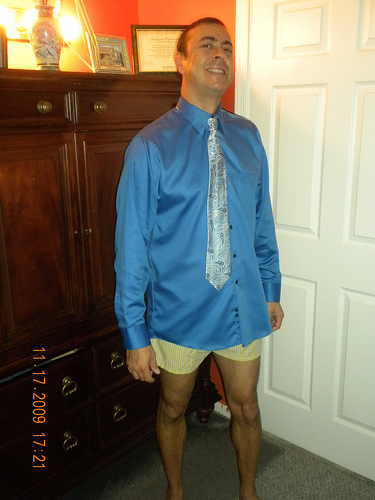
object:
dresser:
[0, 69, 223, 365]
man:
[113, 17, 285, 500]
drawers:
[96, 380, 159, 456]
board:
[98, 5, 125, 27]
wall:
[2, 0, 137, 68]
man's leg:
[149, 333, 201, 499]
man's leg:
[213, 337, 262, 500]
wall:
[223, 89, 235, 108]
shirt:
[113, 95, 281, 351]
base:
[214, 402, 232, 419]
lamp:
[28, 1, 64, 71]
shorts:
[149, 339, 260, 375]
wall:
[210, 356, 231, 419]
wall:
[81, 1, 234, 71]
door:
[234, 1, 375, 481]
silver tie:
[204, 117, 231, 291]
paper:
[137, 29, 185, 72]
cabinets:
[0, 346, 92, 448]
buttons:
[230, 225, 233, 229]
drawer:
[92, 336, 130, 393]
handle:
[62, 376, 78, 397]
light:
[59, 14, 81, 43]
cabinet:
[0, 129, 73, 353]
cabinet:
[73, 123, 150, 320]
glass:
[136, 29, 184, 73]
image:
[98, 43, 124, 67]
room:
[0, 0, 373, 499]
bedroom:
[0, 0, 375, 500]